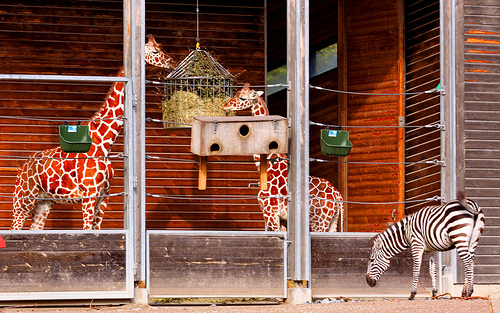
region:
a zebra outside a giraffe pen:
[355, 188, 491, 299]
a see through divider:
[140, 217, 295, 302]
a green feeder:
[315, 121, 357, 152]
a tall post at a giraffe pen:
[273, 0, 314, 300]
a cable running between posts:
[308, 82, 443, 99]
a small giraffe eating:
[226, 81, 346, 231]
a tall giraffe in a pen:
[6, 29, 179, 227]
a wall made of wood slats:
[333, 5, 408, 228]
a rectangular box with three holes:
[189, 112, 294, 161]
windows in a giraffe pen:
[260, 36, 343, 97]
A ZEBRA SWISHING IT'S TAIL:
[349, 184, 487, 304]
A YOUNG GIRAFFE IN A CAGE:
[215, 70, 356, 250]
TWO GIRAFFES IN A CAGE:
[9, 27, 350, 267]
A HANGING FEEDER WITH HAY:
[153, 1, 251, 139]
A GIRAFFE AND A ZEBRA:
[211, 76, 493, 301]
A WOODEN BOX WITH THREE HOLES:
[183, 107, 298, 167]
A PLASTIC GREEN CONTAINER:
[46, 111, 103, 156]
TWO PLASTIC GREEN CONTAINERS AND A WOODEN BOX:
[50, 105, 366, 174]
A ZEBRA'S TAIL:
[450, 183, 487, 221]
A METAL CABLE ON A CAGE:
[300, 74, 458, 108]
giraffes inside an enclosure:
[38, 15, 363, 280]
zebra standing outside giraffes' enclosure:
[306, 180, 486, 300]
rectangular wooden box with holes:
[175, 96, 307, 176]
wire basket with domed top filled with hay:
[146, 20, 241, 131]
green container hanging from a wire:
[50, 101, 100, 161]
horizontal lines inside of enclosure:
[31, 25, 467, 167]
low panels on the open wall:
[5, 207, 395, 302]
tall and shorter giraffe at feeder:
[145, 31, 265, 121]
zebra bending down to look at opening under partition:
[355, 175, 485, 302]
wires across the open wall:
[3, 57, 449, 217]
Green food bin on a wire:
[321, 128, 351, 155]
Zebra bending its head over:
[363, 205, 478, 294]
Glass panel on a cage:
[148, 229, 288, 296]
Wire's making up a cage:
[308, 82, 448, 204]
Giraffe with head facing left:
[226, 83, 346, 236]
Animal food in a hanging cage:
[162, 46, 237, 128]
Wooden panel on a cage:
[453, 5, 498, 285]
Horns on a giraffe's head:
[146, 34, 158, 43]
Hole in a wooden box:
[236, 119, 257, 136]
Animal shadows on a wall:
[145, 184, 245, 231]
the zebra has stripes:
[381, 160, 486, 310]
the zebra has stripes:
[350, 226, 495, 252]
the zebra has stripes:
[367, 191, 492, 256]